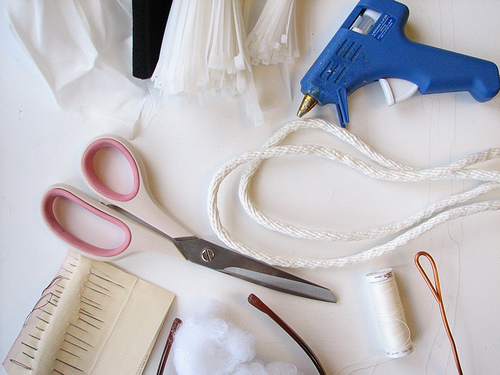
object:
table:
[0, 72, 35, 275]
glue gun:
[296, 1, 499, 129]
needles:
[11, 258, 127, 375]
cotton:
[173, 317, 298, 375]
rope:
[205, 117, 500, 269]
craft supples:
[0, 0, 498, 372]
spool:
[364, 267, 413, 359]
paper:
[117, 303, 150, 337]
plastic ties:
[148, 0, 301, 126]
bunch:
[148, 0, 263, 127]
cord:
[206, 117, 500, 269]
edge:
[247, 294, 265, 308]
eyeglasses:
[248, 294, 327, 375]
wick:
[413, 251, 464, 375]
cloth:
[1, 0, 154, 140]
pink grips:
[39, 134, 196, 271]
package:
[0, 248, 179, 374]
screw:
[201, 249, 216, 262]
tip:
[297, 95, 318, 118]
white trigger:
[378, 77, 418, 106]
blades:
[131, 0, 171, 80]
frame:
[156, 318, 182, 375]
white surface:
[0, 0, 499, 371]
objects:
[37, 133, 338, 304]